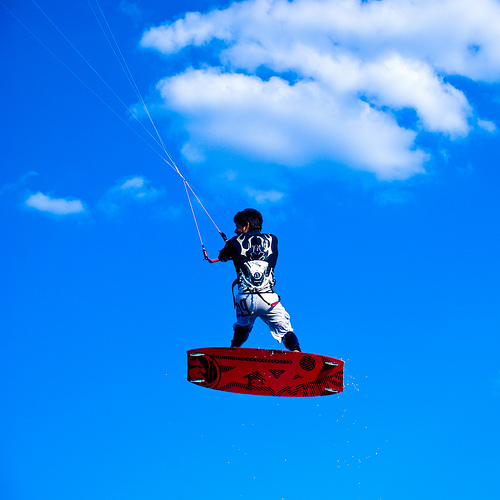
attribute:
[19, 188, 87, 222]
cloud — white, fluffy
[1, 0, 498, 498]
sky — cloudless, blue, clear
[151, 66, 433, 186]
cloud — white, fluffy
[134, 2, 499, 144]
cloud — white, fluffy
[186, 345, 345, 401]
windboard — red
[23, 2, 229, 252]
string — parachute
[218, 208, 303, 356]
man — windsurfing, dark skinned, dark haired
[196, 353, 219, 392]
design — black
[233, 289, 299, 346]
pants — white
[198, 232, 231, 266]
rod — red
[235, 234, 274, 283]
design — decorative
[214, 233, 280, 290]
shirt — white, black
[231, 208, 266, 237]
head — black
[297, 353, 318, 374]
circle — black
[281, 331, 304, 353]
boot — black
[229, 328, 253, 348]
boot — black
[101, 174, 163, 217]
cloud — wispy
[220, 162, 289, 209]
cloud — wispy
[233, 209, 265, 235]
hair — short